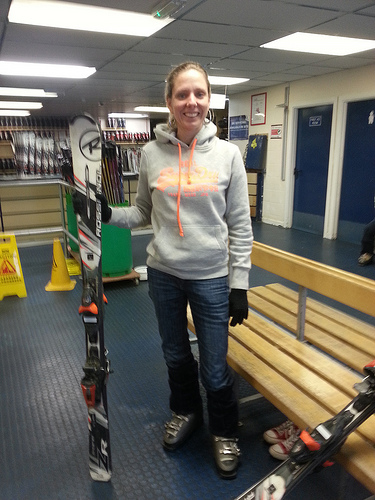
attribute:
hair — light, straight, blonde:
[156, 56, 220, 133]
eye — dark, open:
[192, 88, 207, 100]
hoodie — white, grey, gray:
[100, 126, 270, 288]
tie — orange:
[168, 137, 201, 251]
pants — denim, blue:
[139, 258, 251, 444]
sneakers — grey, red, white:
[159, 410, 246, 484]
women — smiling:
[94, 54, 267, 482]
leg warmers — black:
[164, 362, 247, 440]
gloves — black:
[225, 285, 252, 328]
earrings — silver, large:
[203, 103, 217, 122]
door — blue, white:
[287, 100, 330, 248]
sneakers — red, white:
[263, 413, 310, 465]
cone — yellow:
[42, 236, 80, 298]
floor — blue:
[3, 218, 375, 500]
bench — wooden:
[230, 236, 373, 495]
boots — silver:
[157, 408, 250, 488]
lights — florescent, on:
[3, 1, 194, 46]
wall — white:
[225, 81, 295, 226]